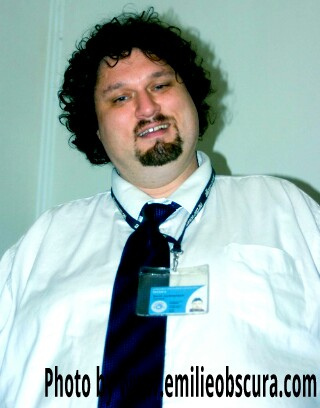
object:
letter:
[301, 373, 316, 397]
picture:
[1, 1, 320, 408]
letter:
[283, 372, 291, 397]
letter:
[268, 372, 279, 397]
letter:
[261, 374, 269, 397]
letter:
[249, 373, 261, 397]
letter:
[242, 373, 251, 396]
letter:
[234, 373, 242, 398]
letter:
[224, 364, 234, 399]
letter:
[214, 373, 225, 397]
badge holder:
[135, 268, 211, 315]